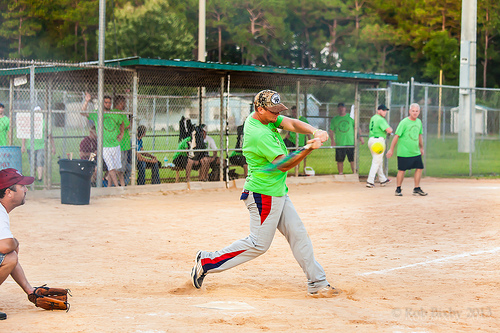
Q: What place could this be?
A: It is a field.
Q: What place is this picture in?
A: It is at the field.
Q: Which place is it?
A: It is a field.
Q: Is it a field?
A: Yes, it is a field.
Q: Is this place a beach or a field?
A: It is a field.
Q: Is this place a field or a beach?
A: It is a field.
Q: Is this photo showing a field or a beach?
A: It is showing a field.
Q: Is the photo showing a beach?
A: No, the picture is showing a field.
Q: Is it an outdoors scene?
A: Yes, it is outdoors.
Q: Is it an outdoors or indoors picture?
A: It is outdoors.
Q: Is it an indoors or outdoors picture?
A: It is outdoors.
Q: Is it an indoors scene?
A: No, it is outdoors.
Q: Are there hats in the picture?
A: Yes, there is a hat.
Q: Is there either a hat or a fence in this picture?
A: Yes, there is a hat.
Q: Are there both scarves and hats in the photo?
A: No, there is a hat but no scarves.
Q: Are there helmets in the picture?
A: No, there are no helmets.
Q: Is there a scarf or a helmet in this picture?
A: No, there are no helmets or scarves.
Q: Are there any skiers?
A: No, there are no skiers.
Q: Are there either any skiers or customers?
A: No, there are no skiers or customers.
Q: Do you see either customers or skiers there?
A: No, there are no skiers or customers.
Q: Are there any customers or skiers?
A: No, there are no skiers or customers.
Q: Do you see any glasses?
A: No, there are no glasses.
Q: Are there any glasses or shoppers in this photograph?
A: No, there are no glasses or shoppers.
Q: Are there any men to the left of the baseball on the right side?
A: Yes, there is a man to the left of the baseball.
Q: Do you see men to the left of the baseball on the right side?
A: Yes, there is a man to the left of the baseball.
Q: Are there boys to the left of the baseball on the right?
A: No, there is a man to the left of the baseball.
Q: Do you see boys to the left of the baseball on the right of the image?
A: No, there is a man to the left of the baseball.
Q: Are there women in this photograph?
A: No, there are no women.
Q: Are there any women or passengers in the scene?
A: No, there are no women or passengers.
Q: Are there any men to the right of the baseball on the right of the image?
A: Yes, there is a man to the right of the baseball.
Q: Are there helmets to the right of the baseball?
A: No, there is a man to the right of the baseball.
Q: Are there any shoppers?
A: No, there are no shoppers.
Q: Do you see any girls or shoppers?
A: No, there are no shoppers or girls.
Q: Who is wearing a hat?
A: The man is wearing a hat.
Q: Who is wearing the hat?
A: The man is wearing a hat.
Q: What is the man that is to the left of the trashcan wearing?
A: The man is wearing a hat.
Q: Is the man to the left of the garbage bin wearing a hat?
A: Yes, the man is wearing a hat.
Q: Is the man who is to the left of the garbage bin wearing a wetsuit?
A: No, the man is wearing a hat.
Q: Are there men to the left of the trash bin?
A: Yes, there is a man to the left of the trash bin.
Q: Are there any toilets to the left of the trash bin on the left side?
A: No, there is a man to the left of the trashcan.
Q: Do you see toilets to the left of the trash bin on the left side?
A: No, there is a man to the left of the trashcan.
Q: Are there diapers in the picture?
A: No, there are no diapers.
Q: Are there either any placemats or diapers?
A: No, there are no diapers or placemats.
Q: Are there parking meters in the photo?
A: No, there are no parking meters.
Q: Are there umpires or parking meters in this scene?
A: No, there are no parking meters or umpires.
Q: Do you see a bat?
A: Yes, there is a bat.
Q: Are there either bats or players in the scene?
A: Yes, there is a bat.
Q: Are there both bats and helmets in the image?
A: No, there is a bat but no helmets.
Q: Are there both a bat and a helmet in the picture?
A: No, there is a bat but no helmets.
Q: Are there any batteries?
A: No, there are no batteries.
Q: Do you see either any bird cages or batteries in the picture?
A: No, there are no batteries or bird cages.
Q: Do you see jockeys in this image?
A: No, there are no jockeys.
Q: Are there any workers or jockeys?
A: No, there are no jockeys or workers.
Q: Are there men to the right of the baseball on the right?
A: Yes, there is a man to the right of the baseball.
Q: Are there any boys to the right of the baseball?
A: No, there is a man to the right of the baseball.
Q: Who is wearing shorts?
A: The man is wearing shorts.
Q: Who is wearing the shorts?
A: The man is wearing shorts.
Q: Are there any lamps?
A: No, there are no lamps.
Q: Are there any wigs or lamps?
A: No, there are no lamps or wigs.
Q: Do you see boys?
A: No, there are no boys.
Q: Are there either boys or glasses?
A: No, there are no boys or glasses.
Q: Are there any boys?
A: No, there are no boys.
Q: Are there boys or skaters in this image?
A: No, there are no boys or skaters.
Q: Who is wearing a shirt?
A: The man is wearing a shirt.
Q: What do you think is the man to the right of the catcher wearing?
A: The man is wearing a shirt.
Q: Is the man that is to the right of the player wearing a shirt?
A: Yes, the man is wearing a shirt.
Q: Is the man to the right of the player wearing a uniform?
A: No, the man is wearing a shirt.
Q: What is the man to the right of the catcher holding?
A: The man is holding the bat.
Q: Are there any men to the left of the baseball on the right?
A: Yes, there is a man to the left of the baseball.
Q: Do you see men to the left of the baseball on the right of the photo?
A: Yes, there is a man to the left of the baseball.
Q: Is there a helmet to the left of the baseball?
A: No, there is a man to the left of the baseball.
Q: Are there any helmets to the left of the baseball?
A: No, there is a man to the left of the baseball.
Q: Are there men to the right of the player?
A: Yes, there is a man to the right of the player.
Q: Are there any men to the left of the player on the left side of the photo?
A: No, the man is to the right of the player.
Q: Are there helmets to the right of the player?
A: No, there is a man to the right of the player.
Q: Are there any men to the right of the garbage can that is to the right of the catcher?
A: Yes, there is a man to the right of the trash bin.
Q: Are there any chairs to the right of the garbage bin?
A: No, there is a man to the right of the garbage bin.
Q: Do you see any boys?
A: No, there are no boys.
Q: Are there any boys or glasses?
A: No, there are no boys or glasses.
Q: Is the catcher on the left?
A: Yes, the catcher is on the left of the image.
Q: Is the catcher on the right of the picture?
A: No, the catcher is on the left of the image.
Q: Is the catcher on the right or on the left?
A: The catcher is on the left of the image.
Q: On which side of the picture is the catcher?
A: The catcher is on the left of the image.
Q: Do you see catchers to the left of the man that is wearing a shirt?
A: Yes, there is a catcher to the left of the man.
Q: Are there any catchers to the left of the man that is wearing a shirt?
A: Yes, there is a catcher to the left of the man.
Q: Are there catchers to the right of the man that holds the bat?
A: No, the catcher is to the left of the man.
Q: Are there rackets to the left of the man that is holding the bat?
A: No, there is a catcher to the left of the man.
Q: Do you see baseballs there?
A: Yes, there is a baseball.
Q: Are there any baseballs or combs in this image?
A: Yes, there is a baseball.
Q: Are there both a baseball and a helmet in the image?
A: No, there is a baseball but no helmets.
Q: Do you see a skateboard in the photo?
A: No, there are no skateboards.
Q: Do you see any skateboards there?
A: No, there are no skateboards.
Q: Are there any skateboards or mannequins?
A: No, there are no skateboards or mannequins.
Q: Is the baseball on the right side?
A: Yes, the baseball is on the right of the image.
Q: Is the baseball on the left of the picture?
A: No, the baseball is on the right of the image.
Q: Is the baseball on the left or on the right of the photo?
A: The baseball is on the right of the image.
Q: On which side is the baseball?
A: The baseball is on the right of the image.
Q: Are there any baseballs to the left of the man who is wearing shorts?
A: Yes, there is a baseball to the left of the man.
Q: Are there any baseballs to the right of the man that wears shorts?
A: No, the baseball is to the left of the man.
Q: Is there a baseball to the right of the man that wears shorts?
A: No, the baseball is to the left of the man.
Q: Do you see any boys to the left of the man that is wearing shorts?
A: No, there is a baseball to the left of the man.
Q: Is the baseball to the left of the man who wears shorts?
A: Yes, the baseball is to the left of the man.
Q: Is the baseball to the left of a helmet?
A: No, the baseball is to the left of the man.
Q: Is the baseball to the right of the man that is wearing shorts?
A: No, the baseball is to the left of the man.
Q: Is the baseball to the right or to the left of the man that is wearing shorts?
A: The baseball is to the left of the man.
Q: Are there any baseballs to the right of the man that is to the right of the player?
A: Yes, there is a baseball to the right of the man.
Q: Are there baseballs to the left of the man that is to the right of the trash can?
A: No, the baseball is to the right of the man.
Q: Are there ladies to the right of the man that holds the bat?
A: No, there is a baseball to the right of the man.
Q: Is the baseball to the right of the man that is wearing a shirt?
A: Yes, the baseball is to the right of the man.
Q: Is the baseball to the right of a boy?
A: No, the baseball is to the right of the man.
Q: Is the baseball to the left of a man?
A: No, the baseball is to the right of a man.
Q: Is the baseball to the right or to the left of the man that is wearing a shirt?
A: The baseball is to the right of the man.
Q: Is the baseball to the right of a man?
A: Yes, the baseball is to the right of a man.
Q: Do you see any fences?
A: Yes, there is a fence.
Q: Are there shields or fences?
A: Yes, there is a fence.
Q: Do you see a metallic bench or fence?
A: Yes, there is a metal fence.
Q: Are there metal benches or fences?
A: Yes, there is a metal fence.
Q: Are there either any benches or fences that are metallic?
A: Yes, the fence is metallic.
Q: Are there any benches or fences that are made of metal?
A: Yes, the fence is made of metal.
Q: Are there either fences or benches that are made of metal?
A: Yes, the fence is made of metal.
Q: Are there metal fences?
A: Yes, there is a metal fence.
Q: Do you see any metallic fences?
A: Yes, there is a metal fence.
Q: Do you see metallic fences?
A: Yes, there is a metal fence.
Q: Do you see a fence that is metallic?
A: Yes, there is a fence that is metallic.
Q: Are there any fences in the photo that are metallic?
A: Yes, there is a fence that is metallic.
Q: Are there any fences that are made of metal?
A: Yes, there is a fence that is made of metal.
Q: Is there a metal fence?
A: Yes, there is a fence that is made of metal.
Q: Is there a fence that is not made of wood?
A: Yes, there is a fence that is made of metal.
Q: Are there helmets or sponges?
A: No, there are no helmets or sponges.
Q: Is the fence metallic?
A: Yes, the fence is metallic.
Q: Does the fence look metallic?
A: Yes, the fence is metallic.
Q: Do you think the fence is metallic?
A: Yes, the fence is metallic.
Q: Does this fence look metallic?
A: Yes, the fence is metallic.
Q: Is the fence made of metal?
A: Yes, the fence is made of metal.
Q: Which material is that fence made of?
A: The fence is made of metal.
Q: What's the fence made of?
A: The fence is made of metal.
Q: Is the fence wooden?
A: No, the fence is metallic.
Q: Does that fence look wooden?
A: No, the fence is metallic.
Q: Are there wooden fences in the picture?
A: No, there is a fence but it is metallic.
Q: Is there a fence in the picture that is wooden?
A: No, there is a fence but it is metallic.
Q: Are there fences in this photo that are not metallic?
A: No, there is a fence but it is metallic.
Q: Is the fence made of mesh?
A: No, the fence is made of metal.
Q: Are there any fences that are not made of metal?
A: No, there is a fence but it is made of metal.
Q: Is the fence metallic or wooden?
A: The fence is metallic.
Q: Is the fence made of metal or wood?
A: The fence is made of metal.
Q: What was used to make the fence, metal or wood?
A: The fence is made of metal.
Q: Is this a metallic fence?
A: Yes, this is a metallic fence.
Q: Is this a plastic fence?
A: No, this is a metallic fence.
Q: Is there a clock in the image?
A: No, there are no clocks.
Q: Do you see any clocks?
A: No, there are no clocks.